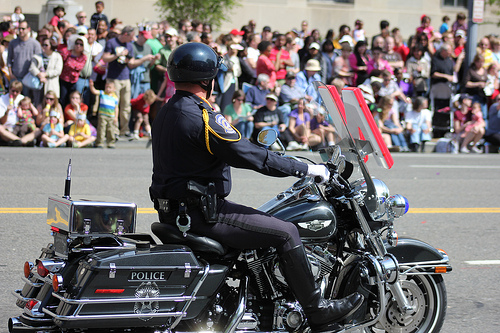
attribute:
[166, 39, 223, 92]
helmet — black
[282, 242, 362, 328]
boot — black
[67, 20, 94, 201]
antenna — silver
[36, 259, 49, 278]
light — red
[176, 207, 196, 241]
handcuffs — belted, silver, metal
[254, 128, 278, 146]
mirror — rear view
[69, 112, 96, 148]
boy — little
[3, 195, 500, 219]
line — yellow, white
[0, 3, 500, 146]
crowd — sitting, present, standing, watching, lined up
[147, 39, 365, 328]
officer — coated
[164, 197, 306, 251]
pants — black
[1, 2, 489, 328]
image — colorful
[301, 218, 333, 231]
logo — police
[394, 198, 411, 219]
light — blue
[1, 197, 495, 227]
stripe — yellow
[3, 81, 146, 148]
children — seated